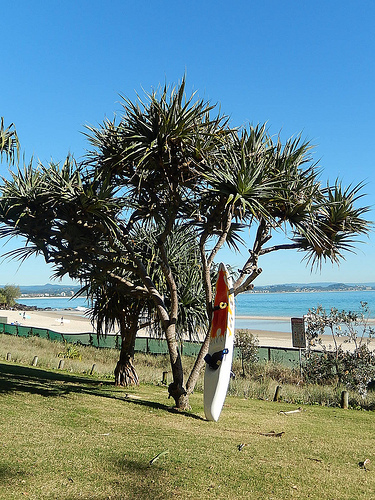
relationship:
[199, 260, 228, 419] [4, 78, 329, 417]
kayak by a tree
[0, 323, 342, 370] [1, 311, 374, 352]
fence in front of beach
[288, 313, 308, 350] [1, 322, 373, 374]
sign by fence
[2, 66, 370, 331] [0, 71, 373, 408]
leaves on tree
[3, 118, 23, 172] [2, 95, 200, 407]
leaves on tree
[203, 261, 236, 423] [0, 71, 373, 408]
kayak on tree